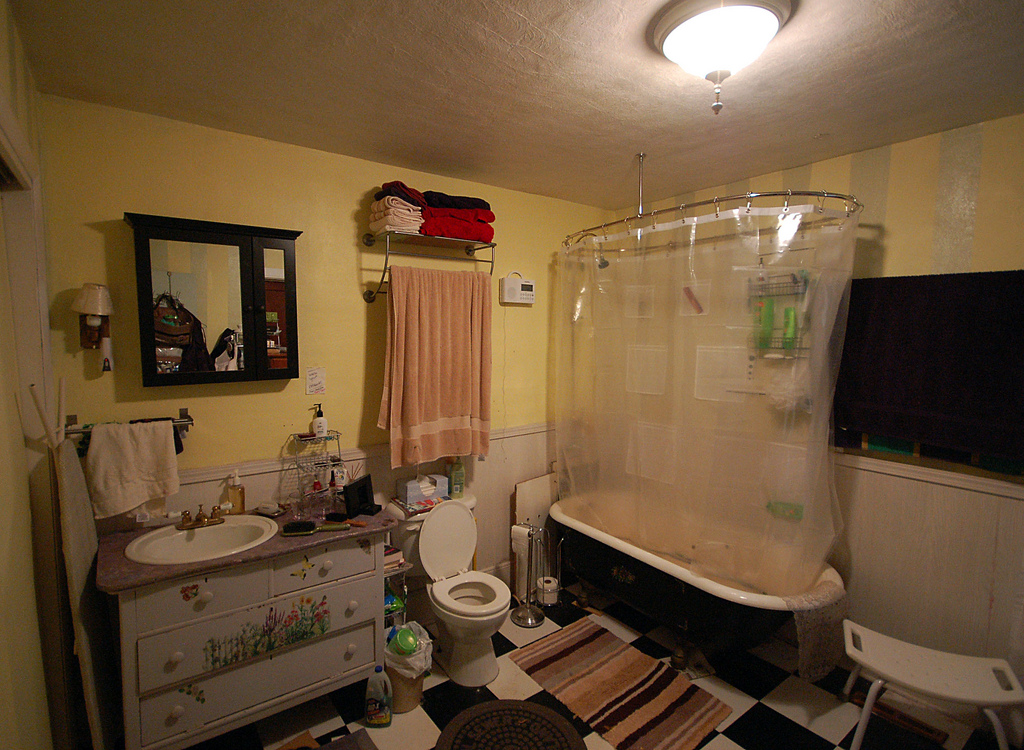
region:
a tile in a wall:
[916, 560, 937, 593]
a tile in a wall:
[952, 579, 994, 640]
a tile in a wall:
[913, 621, 958, 666]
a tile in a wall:
[506, 427, 545, 479]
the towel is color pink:
[362, 257, 502, 470]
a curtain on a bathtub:
[525, 156, 890, 695]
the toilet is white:
[407, 485, 524, 700]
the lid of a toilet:
[405, 496, 497, 589]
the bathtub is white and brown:
[525, 480, 855, 697]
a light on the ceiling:
[619, 3, 822, 130]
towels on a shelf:
[350, 169, 512, 280]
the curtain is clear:
[563, 195, 852, 594]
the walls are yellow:
[5, 107, 1023, 744]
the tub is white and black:
[539, 496, 833, 702]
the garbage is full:
[378, 625, 424, 714]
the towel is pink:
[363, 265, 496, 472]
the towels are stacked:
[369, 187, 493, 246]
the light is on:
[667, 4, 801, 116]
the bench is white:
[824, 632, 1021, 743]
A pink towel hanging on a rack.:
[377, 265, 494, 466]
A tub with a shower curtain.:
[551, 170, 862, 662]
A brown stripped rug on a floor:
[512, 614, 753, 745]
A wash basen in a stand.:
[96, 466, 395, 741]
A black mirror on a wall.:
[123, 211, 302, 388]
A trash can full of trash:
[383, 616, 431, 712]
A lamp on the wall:
[74, 283, 109, 361]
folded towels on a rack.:
[379, 182, 496, 239]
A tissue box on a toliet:
[403, 467, 451, 506]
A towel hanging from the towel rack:
[369, 261, 499, 474]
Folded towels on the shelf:
[362, 175, 500, 251]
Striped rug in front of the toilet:
[508, 611, 736, 745]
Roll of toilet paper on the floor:
[533, 565, 562, 607]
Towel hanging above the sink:
[80, 424, 183, 522]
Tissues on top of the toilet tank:
[397, 463, 455, 517]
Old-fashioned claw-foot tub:
[546, 482, 850, 683]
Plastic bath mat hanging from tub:
[783, 571, 851, 683]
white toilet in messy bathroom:
[397, 499, 509, 687]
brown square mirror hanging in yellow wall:
[131, 209, 300, 391]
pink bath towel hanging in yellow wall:
[374, 260, 501, 472]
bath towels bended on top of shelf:
[368, 178, 495, 246]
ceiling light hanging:
[649, 1, 795, 94]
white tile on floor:
[483, 596, 548, 644]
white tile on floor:
[474, 656, 538, 702]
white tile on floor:
[368, 710, 448, 746]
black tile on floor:
[418, 675, 501, 732]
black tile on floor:
[521, 681, 591, 738]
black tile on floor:
[719, 704, 827, 746]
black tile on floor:
[699, 638, 789, 697]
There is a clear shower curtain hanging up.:
[568, 206, 843, 567]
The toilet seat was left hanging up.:
[419, 487, 512, 620]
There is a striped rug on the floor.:
[502, 595, 731, 744]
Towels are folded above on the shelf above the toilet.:
[350, 168, 503, 236]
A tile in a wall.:
[929, 128, 980, 179]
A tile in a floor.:
[483, 645, 532, 700]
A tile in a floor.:
[517, 683, 585, 731]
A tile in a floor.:
[625, 637, 671, 669]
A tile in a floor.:
[672, 668, 750, 736]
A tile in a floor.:
[705, 699, 830, 747]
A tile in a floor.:
[489, 593, 587, 657]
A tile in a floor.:
[723, 694, 778, 746]